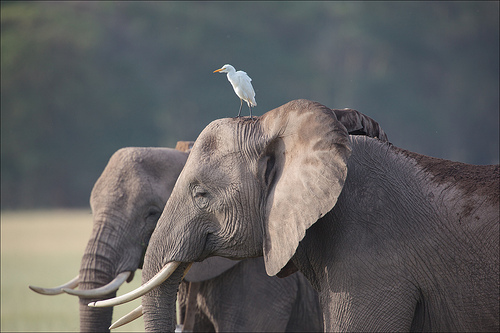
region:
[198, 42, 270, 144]
bird on elephant's head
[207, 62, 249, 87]
head of the bird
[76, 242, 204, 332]
white tusk on elephant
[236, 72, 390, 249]
ear of the elephant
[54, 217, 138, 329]
trunk on the elephant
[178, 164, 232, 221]
eye of the elephant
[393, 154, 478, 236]
back of the elephant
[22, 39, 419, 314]
two elephants in the photo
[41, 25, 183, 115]
blurry background of photo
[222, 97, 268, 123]
legs of the bird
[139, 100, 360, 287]
head of an elephant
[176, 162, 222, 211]
eye of an elephant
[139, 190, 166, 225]
eye of an elephant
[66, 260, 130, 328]
nose of an elephant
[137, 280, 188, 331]
nose of an elephant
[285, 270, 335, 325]
leg of an elephant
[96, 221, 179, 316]
trunk of an elephant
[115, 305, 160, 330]
trunk of an elephant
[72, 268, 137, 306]
trunk of an elephant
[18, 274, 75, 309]
trunk of an elephant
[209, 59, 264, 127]
unusual hat, with legs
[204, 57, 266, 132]
cattle egret hanging out [or hanging ON, whatever the case may be]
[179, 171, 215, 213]
elephant throws side eye @ photographer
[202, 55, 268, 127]
not breeding season plumage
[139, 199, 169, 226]
a placid+content expression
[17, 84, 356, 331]
two elephants share elephant joke, possibly about unusual headwear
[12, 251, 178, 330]
at least 3 of 4 very upturned white tusks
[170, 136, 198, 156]
this _has_ to be a piece of wood behind the elephants, unless the furthest one found an unusual hat too!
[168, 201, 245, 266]
smiling mouth surrounded by many laugh lines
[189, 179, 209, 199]
a large eyelid with long elephant eyelashes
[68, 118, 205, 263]
head of an elephant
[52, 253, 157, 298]
trunk of an elephant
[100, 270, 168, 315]
trunk of an elephant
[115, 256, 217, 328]
nose of an elephant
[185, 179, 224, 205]
eye of an elephant